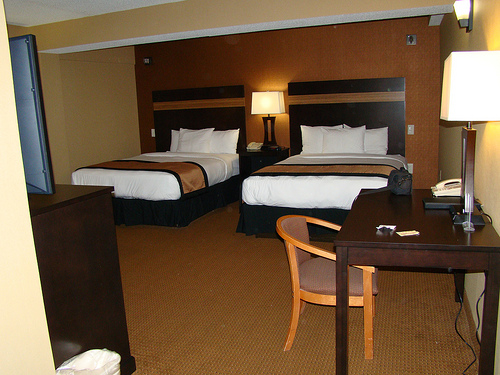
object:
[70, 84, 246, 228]
bed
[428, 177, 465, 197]
phone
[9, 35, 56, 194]
back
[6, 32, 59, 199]
television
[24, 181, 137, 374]
tv stand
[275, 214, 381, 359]
chair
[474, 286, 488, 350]
cord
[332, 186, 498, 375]
table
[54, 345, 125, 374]
trash can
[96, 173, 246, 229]
bedskirt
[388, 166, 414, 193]
purse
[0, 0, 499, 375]
room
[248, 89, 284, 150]
lamp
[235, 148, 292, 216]
nightstand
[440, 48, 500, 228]
lamp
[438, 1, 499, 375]
wall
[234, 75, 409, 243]
beds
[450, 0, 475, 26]
light